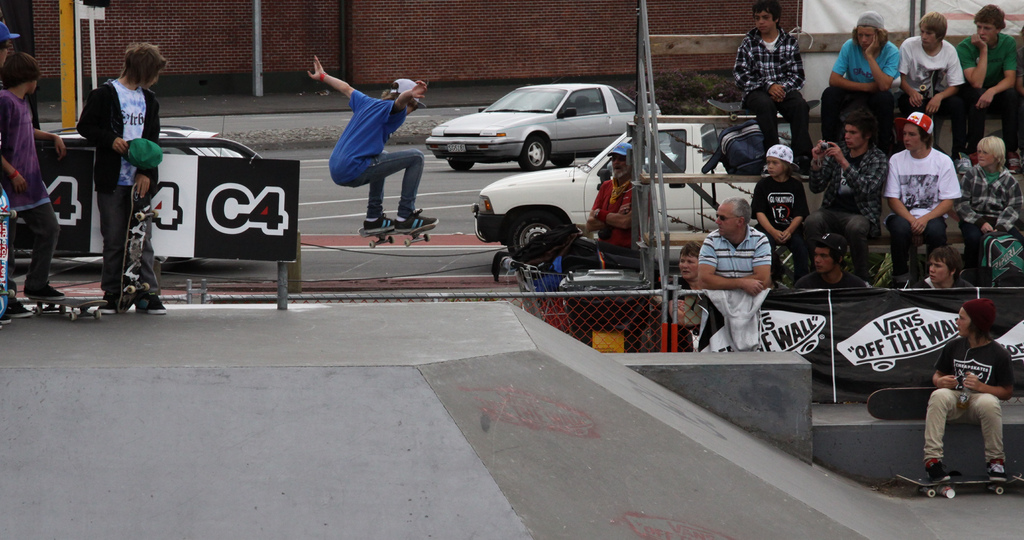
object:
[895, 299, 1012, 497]
person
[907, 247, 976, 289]
person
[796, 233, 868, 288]
person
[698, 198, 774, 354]
person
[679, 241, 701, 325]
person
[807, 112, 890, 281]
person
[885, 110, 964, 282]
person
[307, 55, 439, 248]
skateboarder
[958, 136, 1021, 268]
person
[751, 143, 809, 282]
person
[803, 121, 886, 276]
person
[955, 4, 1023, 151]
person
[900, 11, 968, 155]
person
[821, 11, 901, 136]
person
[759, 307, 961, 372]
signs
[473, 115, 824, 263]
truck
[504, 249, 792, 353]
side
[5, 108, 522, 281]
road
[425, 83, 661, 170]
car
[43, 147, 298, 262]
signs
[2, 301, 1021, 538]
ramp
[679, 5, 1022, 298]
bleachers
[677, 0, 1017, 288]
people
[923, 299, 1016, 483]
skater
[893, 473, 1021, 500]
skateboard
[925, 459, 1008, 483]
feet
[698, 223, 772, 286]
shirt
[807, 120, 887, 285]
guy